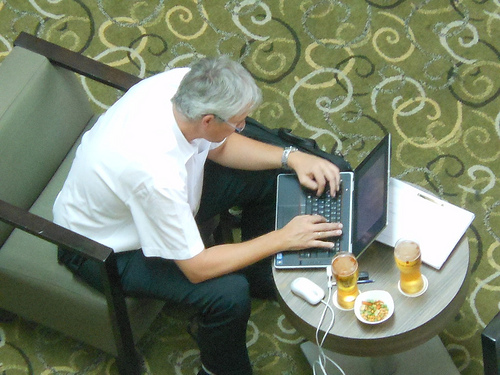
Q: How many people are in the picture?
A: One.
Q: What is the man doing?
A: Typing.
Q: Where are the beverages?
A: On the table.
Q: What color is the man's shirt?
A: White.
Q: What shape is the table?
A: Round.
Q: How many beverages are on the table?
A: Two.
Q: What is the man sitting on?
A: A chair.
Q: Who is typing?
A: A man.